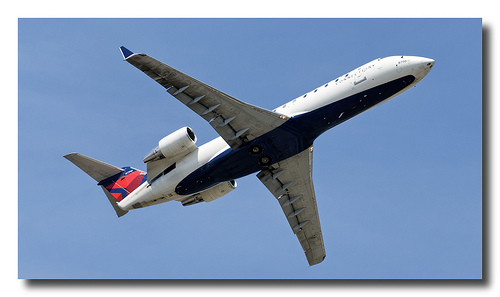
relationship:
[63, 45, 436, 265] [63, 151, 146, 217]
airplane has tail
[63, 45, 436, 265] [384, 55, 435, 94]
airplane has nose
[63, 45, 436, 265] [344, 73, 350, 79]
airplane has window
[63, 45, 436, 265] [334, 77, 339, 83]
airplane has window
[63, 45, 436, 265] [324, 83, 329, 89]
airplane has window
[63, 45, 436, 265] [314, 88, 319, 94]
airplane has window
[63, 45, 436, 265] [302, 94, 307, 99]
airplane has window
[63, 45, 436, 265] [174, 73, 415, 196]
airplane has bottom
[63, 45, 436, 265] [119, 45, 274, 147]
airplane has wing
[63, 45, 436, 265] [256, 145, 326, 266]
airplane has wing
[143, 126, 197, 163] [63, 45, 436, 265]
engine in back of airplane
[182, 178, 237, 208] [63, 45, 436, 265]
engine in back of airplane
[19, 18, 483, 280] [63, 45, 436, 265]
sky behind airplane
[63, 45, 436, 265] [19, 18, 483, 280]
airplane in sky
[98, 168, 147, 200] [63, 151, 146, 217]
design on tail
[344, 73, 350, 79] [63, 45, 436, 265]
window on side of airplane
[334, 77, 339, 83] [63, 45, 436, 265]
window on side of airplane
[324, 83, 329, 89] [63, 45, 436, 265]
window on side of airplane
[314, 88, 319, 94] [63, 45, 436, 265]
window on side of airplane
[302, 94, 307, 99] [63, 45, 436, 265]
window on side of airplane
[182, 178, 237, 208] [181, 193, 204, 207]
engine has ending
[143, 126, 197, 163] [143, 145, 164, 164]
engine has tip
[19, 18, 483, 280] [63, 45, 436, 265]
sky above airplane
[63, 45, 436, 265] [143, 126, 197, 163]
airplane has engine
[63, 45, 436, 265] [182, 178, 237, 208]
airplane has engine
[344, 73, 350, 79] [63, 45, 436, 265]
window on airplane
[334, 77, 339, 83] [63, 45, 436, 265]
window on airplane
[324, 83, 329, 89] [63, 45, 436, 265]
window on airplane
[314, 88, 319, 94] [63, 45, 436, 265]
window on airplane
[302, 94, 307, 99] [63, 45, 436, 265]
window on airplane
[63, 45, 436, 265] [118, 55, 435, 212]
airplane has fuselage